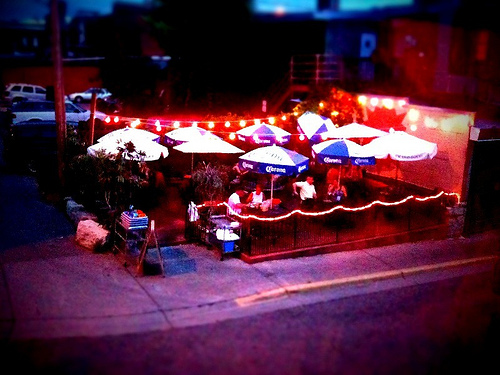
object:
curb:
[0, 241, 496, 341]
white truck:
[13, 101, 110, 125]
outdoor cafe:
[84, 95, 479, 280]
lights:
[407, 109, 419, 121]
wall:
[330, 91, 475, 213]